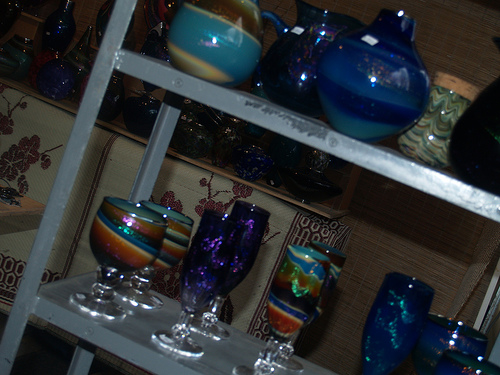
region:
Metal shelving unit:
[15, 0, 497, 358]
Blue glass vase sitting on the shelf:
[317, 2, 450, 149]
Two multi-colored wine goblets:
[70, 177, 197, 320]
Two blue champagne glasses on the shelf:
[184, 188, 274, 333]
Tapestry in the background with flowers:
[5, 75, 335, 362]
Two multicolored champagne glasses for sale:
[247, 201, 354, 366]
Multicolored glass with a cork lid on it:
[395, 60, 485, 174]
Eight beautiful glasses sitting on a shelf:
[47, 188, 497, 373]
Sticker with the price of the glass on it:
[146, 322, 177, 356]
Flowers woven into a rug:
[0, 84, 69, 217]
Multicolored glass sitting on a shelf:
[77, 195, 168, 325]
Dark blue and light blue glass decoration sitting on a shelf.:
[315, 5, 427, 142]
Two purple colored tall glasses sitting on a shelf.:
[152, 200, 271, 363]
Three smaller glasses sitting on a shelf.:
[0, 1, 86, 101]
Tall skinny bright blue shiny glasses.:
[360, 270, 435, 374]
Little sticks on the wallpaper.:
[2, 92, 25, 114]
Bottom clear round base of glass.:
[70, 292, 127, 320]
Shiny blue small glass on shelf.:
[232, 142, 276, 180]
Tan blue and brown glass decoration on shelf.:
[167, 0, 266, 84]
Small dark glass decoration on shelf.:
[122, 89, 163, 138]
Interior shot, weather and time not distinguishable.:
[7, 8, 494, 373]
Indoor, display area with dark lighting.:
[15, 16, 495, 370]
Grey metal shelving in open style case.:
[25, 65, 498, 370]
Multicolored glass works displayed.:
[86, 6, 499, 373]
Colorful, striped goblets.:
[77, 197, 182, 324]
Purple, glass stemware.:
[158, 199, 265, 359]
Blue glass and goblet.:
[360, 272, 489, 373]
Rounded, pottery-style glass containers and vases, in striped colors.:
[163, 2, 499, 189]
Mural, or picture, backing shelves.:
[9, 119, 294, 291]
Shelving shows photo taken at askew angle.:
[13, 17, 490, 371]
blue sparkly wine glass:
[197, 194, 274, 359]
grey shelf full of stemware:
[62, 157, 434, 372]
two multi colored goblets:
[92, 182, 189, 326]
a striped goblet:
[78, 189, 160, 333]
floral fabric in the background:
[7, 104, 72, 227]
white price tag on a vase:
[361, 25, 382, 53]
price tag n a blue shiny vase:
[355, 28, 381, 58]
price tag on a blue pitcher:
[285, 18, 304, 40]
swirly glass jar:
[401, 63, 481, 172]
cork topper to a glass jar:
[434, 64, 487, 107]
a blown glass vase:
[307, 5, 437, 142]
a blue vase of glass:
[316, 7, 428, 142]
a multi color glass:
[71, 194, 163, 322]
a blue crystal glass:
[151, 206, 247, 358]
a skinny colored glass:
[236, 247, 332, 374]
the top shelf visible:
[100, 44, 499, 220]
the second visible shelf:
[34, 270, 338, 374]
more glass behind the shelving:
[0, 0, 327, 215]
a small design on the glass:
[286, 263, 313, 302]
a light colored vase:
[400, 67, 478, 165]